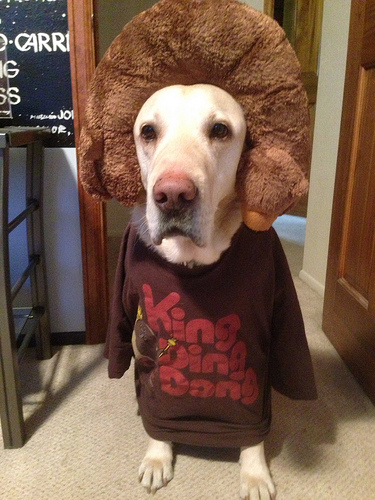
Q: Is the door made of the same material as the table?
A: No, the door is made of wood and the table is made of metal.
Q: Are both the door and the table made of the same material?
A: No, the door is made of wood and the table is made of metal.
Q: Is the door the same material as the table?
A: No, the door is made of wood and the table is made of metal.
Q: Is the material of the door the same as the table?
A: No, the door is made of wood and the table is made of metal.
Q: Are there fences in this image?
A: No, there are no fences.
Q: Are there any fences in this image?
A: No, there are no fences.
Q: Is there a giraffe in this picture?
A: No, there are no giraffes.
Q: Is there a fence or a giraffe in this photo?
A: No, there are no giraffes or fences.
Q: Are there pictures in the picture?
A: No, there are no pictures.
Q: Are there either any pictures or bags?
A: No, there are no pictures or bags.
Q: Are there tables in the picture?
A: Yes, there is a table.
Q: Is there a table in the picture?
A: Yes, there is a table.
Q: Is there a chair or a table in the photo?
A: Yes, there is a table.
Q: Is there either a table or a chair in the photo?
A: Yes, there is a table.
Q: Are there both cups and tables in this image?
A: No, there is a table but no cups.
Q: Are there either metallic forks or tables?
A: Yes, there is a metal table.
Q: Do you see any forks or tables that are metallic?
A: Yes, the table is metallic.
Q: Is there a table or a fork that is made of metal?
A: Yes, the table is made of metal.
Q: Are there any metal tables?
A: Yes, there is a metal table.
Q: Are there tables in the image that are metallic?
A: Yes, there is a table that is metallic.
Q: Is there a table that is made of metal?
A: Yes, there is a table that is made of metal.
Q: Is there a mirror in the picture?
A: No, there are no mirrors.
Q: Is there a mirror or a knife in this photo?
A: No, there are no mirrors or knives.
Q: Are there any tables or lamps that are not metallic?
A: No, there is a table but it is metallic.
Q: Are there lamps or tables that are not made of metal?
A: No, there is a table but it is made of metal.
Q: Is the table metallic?
A: Yes, the table is metallic.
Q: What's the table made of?
A: The table is made of metal.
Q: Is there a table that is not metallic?
A: No, there is a table but it is metallic.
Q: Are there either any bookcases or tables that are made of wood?
A: No, there is a table but it is made of metal.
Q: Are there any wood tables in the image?
A: No, there is a table but it is made of metal.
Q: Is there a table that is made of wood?
A: No, there is a table but it is made of metal.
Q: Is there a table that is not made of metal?
A: No, there is a table but it is made of metal.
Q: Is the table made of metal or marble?
A: The table is made of metal.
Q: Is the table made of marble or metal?
A: The table is made of metal.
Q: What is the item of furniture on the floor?
A: The piece of furniture is a table.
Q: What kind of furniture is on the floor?
A: The piece of furniture is a table.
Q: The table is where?
A: The table is on the floor.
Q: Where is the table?
A: The table is on the floor.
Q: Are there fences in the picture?
A: No, there are no fences.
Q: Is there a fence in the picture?
A: No, there are no fences.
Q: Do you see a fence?
A: No, there are no fences.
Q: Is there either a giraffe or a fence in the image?
A: No, there are no fences or giraffes.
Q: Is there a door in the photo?
A: Yes, there is a door.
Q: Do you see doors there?
A: Yes, there is a door.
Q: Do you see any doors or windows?
A: Yes, there is a door.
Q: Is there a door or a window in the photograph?
A: Yes, there is a door.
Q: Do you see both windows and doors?
A: No, there is a door but no windows.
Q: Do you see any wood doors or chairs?
A: Yes, there is a wood door.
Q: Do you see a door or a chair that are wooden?
A: Yes, the door is wooden.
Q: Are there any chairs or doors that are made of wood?
A: Yes, the door is made of wood.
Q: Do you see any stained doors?
A: Yes, there is a stained door.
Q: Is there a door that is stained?
A: Yes, there is a door that is stained.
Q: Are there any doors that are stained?
A: Yes, there is a door that is stained.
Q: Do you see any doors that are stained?
A: Yes, there is a door that is stained.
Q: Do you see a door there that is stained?
A: Yes, there is a door that is stained.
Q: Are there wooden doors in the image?
A: Yes, there is a wood door.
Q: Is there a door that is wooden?
A: Yes, there is a door that is wooden.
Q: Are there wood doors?
A: Yes, there is a door that is made of wood.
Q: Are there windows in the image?
A: No, there are no windows.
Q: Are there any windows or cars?
A: No, there are no windows or cars.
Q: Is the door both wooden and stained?
A: Yes, the door is wooden and stained.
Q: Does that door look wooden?
A: Yes, the door is wooden.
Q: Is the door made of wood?
A: Yes, the door is made of wood.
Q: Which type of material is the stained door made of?
A: The door is made of wood.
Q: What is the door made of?
A: The door is made of wood.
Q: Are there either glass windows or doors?
A: No, there is a door but it is wooden.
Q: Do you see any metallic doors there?
A: No, there is a door but it is wooden.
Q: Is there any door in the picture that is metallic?
A: No, there is a door but it is wooden.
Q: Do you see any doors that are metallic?
A: No, there is a door but it is wooden.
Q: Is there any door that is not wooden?
A: No, there is a door but it is wooden.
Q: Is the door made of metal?
A: No, the door is made of wood.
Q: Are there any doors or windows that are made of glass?
A: No, there is a door but it is made of wood.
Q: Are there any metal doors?
A: No, there is a door but it is made of wood.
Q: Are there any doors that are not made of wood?
A: No, there is a door but it is made of wood.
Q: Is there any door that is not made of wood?
A: No, there is a door but it is made of wood.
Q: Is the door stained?
A: Yes, the door is stained.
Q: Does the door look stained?
A: Yes, the door is stained.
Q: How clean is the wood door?
A: The door is stained.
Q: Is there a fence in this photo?
A: No, there are no fences.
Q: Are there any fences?
A: No, there are no fences.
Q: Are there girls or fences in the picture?
A: No, there are no fences or girls.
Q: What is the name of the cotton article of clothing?
A: The clothing item is a shirt.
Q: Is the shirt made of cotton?
A: Yes, the shirt is made of cotton.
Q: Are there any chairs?
A: No, there are no chairs.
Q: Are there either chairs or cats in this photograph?
A: No, there are no chairs or cats.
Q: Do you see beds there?
A: No, there are no beds.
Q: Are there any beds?
A: No, there are no beds.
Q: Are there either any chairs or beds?
A: No, there are no beds or chairs.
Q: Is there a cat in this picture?
A: No, there are no cats.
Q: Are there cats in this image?
A: No, there are no cats.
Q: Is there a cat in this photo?
A: No, there are no cats.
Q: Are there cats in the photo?
A: No, there are no cats.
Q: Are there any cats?
A: No, there are no cats.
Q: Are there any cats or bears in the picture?
A: No, there are no cats or bears.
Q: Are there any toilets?
A: No, there are no toilets.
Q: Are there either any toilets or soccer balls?
A: No, there are no toilets or soccer balls.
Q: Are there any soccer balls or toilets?
A: No, there are no toilets or soccer balls.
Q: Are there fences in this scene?
A: No, there are no fences.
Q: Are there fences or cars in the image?
A: No, there are no fences or cars.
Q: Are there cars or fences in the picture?
A: No, there are no fences or cars.